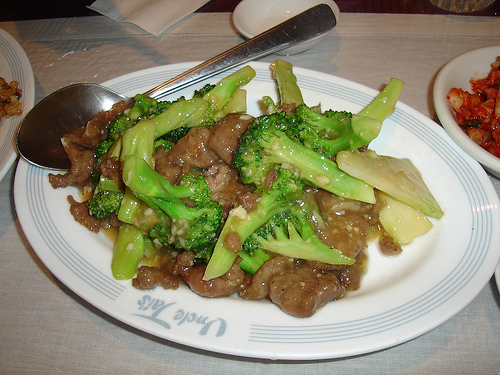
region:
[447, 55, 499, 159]
sweet and sour chicken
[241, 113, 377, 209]
broccoli spear on plate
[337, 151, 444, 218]
white onion on plate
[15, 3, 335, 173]
silver metal spoon on plate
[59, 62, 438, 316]
broccoli and beef on plate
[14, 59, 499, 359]
white and blue plate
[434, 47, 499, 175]
white bowl on table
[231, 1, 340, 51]
white ceramic bowl on table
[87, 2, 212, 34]
white paper napkin on table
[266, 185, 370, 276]
broccoli on a plate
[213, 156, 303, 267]
broccoli on a plate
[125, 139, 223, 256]
broccoli on a plate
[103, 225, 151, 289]
broccoli on a plate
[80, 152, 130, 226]
broccoli on a plate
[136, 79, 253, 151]
broccoli on a plate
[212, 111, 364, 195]
broccoli on a plate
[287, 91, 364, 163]
broccoli on a plate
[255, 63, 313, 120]
broccoli on a plate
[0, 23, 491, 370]
plate on a table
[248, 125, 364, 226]
broccoli has been cooked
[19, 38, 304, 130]
silver spoon on the plate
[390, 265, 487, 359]
blue and white plate on the table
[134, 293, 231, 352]
restaurant name on the plate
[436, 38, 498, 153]
white bowl with food in it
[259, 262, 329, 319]
brown meat in gravy on the plate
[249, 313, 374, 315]
thin blue lines on the plate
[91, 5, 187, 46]
napkin on the table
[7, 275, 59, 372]
white table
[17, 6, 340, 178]
one shiny metal tablespoon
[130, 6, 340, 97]
shiny metal spoon handle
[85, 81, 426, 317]
broccoli and meat on plate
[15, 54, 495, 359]
cooked food on white plate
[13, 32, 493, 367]
round white plate with food on it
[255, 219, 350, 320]
piece of broccoli next to meat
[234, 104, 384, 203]
green broccoli stem with minced garlic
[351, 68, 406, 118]
light green broccoli stem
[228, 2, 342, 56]
little round bowl behind spoon handle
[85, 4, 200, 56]
white napkin on edge of table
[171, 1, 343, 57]
spoon on a plate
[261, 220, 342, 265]
brocoli on a plate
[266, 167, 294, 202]
brocoli on a plate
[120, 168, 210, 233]
brocoli on a plate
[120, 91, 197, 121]
brocoli on a plate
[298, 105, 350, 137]
brocoli on a plate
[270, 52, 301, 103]
brocoli on a plate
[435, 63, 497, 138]
food on a plate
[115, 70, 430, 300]
food on a plate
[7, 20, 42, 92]
plate on a table